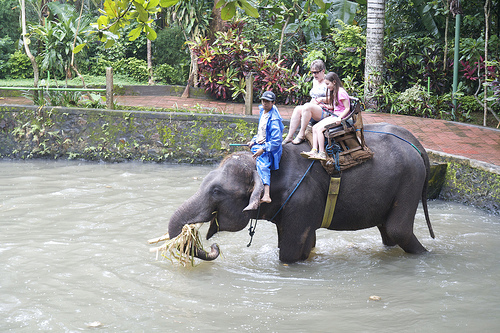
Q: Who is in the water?
A: Elephant.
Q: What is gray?
A: An elephant.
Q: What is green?
A: Bushes.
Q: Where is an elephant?
A: In the water.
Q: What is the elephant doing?
A: Eating.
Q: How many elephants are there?
A: One.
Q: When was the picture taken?
A: Daytime.